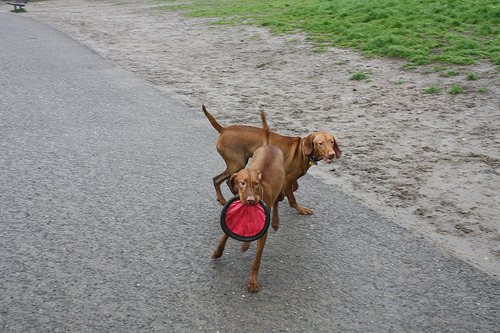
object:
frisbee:
[220, 196, 271, 242]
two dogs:
[202, 103, 341, 293]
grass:
[347, 72, 366, 82]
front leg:
[249, 231, 268, 279]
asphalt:
[0, 172, 176, 331]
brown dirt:
[0, 0, 500, 284]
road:
[0, 0, 500, 332]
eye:
[240, 180, 247, 186]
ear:
[301, 133, 315, 155]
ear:
[332, 135, 340, 160]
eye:
[314, 139, 324, 144]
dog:
[211, 108, 289, 292]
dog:
[200, 105, 342, 215]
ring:
[218, 195, 271, 243]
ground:
[2, 0, 499, 332]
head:
[303, 129, 343, 162]